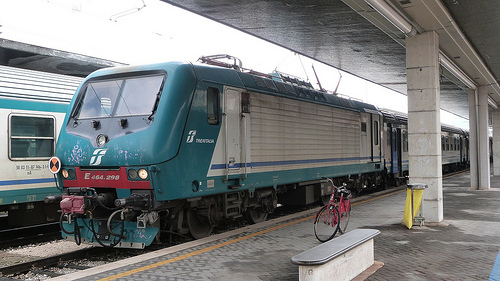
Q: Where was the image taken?
A: It was taken at the train station.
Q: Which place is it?
A: It is a train station.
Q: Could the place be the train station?
A: Yes, it is the train station.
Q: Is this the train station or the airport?
A: It is the train station.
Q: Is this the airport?
A: No, it is the train station.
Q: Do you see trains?
A: Yes, there is a train.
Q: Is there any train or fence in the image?
A: Yes, there is a train.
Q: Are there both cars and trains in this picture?
A: Yes, there are both a train and a car.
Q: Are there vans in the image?
A: No, there are no vans.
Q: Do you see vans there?
A: No, there are no vans.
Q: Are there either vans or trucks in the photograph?
A: No, there are no vans or trucks.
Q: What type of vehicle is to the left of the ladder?
A: The vehicle is a train.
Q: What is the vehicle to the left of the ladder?
A: The vehicle is a train.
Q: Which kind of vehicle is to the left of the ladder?
A: The vehicle is a train.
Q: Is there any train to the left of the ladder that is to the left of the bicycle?
A: Yes, there is a train to the left of the ladder.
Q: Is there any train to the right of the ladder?
A: No, the train is to the left of the ladder.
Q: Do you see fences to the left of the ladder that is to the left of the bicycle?
A: No, there is a train to the left of the ladder.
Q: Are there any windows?
A: Yes, there is a window.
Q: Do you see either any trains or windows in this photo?
A: Yes, there is a window.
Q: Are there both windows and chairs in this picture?
A: No, there is a window but no chairs.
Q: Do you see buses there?
A: No, there are no buses.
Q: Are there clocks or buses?
A: No, there are no buses or clocks.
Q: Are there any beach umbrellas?
A: No, there are no beach umbrellas.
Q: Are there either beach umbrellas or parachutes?
A: No, there are no beach umbrellas or parachutes.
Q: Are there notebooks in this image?
A: No, there are no notebooks.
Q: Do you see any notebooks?
A: No, there are no notebooks.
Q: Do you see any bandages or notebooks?
A: No, there are no notebooks or bandages.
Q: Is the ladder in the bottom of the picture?
A: Yes, the ladder is in the bottom of the image.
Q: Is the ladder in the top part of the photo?
A: No, the ladder is in the bottom of the image.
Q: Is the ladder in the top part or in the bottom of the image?
A: The ladder is in the bottom of the image.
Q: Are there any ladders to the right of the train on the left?
A: Yes, there is a ladder to the right of the train.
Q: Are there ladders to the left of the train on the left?
A: No, the ladder is to the right of the train.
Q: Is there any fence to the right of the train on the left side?
A: No, there is a ladder to the right of the train.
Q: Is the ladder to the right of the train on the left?
A: Yes, the ladder is to the right of the train.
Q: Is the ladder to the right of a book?
A: No, the ladder is to the right of the train.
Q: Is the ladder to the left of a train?
A: No, the ladder is to the right of a train.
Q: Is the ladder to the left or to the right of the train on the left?
A: The ladder is to the right of the train.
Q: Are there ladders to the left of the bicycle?
A: Yes, there is a ladder to the left of the bicycle.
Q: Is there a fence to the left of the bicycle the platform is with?
A: No, there is a ladder to the left of the bicycle.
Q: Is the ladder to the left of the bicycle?
A: Yes, the ladder is to the left of the bicycle.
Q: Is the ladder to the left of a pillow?
A: No, the ladder is to the left of the bicycle.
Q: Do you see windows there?
A: Yes, there are windows.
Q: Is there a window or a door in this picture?
A: Yes, there are windows.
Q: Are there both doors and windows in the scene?
A: Yes, there are both windows and a door.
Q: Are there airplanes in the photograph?
A: No, there are no airplanes.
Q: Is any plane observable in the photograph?
A: No, there are no airplanes.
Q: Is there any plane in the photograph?
A: No, there are no airplanes.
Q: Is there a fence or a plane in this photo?
A: No, there are no airplanes or fences.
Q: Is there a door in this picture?
A: Yes, there is a door.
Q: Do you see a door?
A: Yes, there is a door.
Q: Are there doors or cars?
A: Yes, there is a door.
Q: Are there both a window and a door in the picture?
A: Yes, there are both a door and a window.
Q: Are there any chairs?
A: No, there are no chairs.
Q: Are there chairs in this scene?
A: No, there are no chairs.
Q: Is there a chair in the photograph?
A: No, there are no chairs.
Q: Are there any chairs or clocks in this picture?
A: No, there are no chairs or clocks.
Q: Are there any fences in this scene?
A: No, there are no fences.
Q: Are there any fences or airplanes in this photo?
A: No, there are no fences or airplanes.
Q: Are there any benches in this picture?
A: Yes, there is a bench.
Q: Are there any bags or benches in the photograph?
A: Yes, there is a bench.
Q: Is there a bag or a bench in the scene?
A: Yes, there is a bench.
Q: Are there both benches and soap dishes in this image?
A: No, there is a bench but no soap dishes.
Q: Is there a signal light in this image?
A: No, there are no traffic lights.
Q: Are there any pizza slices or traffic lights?
A: No, there are no traffic lights or pizza slices.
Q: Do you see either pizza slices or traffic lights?
A: No, there are no traffic lights or pizza slices.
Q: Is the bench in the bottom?
A: Yes, the bench is in the bottom of the image.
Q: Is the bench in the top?
A: No, the bench is in the bottom of the image.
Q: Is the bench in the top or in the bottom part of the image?
A: The bench is in the bottom of the image.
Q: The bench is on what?
A: The bench is on the platform.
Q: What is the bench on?
A: The bench is on the platform.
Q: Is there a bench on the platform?
A: Yes, there is a bench on the platform.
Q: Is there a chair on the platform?
A: No, there is a bench on the platform.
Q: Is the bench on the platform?
A: Yes, the bench is on the platform.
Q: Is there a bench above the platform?
A: Yes, there is a bench above the platform.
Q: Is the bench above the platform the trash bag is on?
A: Yes, the bench is above the platform.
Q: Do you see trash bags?
A: Yes, there is a trash bag.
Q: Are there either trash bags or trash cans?
A: Yes, there is a trash bag.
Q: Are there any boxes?
A: No, there are no boxes.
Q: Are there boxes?
A: No, there are no boxes.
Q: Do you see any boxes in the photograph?
A: No, there are no boxes.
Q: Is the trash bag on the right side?
A: Yes, the trash bag is on the right of the image.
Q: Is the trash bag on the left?
A: No, the trash bag is on the right of the image.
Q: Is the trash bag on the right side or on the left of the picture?
A: The trash bag is on the right of the image.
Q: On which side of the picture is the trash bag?
A: The trash bag is on the right of the image.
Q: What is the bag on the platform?
A: The bag is a trash bag.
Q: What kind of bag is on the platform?
A: The bag is a trash bag.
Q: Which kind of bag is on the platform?
A: The bag is a trash bag.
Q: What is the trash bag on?
A: The trash bag is on the platform.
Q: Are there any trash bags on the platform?
A: Yes, there is a trash bag on the platform.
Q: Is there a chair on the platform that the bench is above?
A: No, there is a trash bag on the platform.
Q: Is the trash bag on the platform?
A: Yes, the trash bag is on the platform.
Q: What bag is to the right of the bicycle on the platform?
A: The bag is a trash bag.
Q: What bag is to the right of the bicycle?
A: The bag is a trash bag.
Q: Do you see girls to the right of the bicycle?
A: No, there is a trash bag to the right of the bicycle.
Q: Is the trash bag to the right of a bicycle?
A: Yes, the trash bag is to the right of a bicycle.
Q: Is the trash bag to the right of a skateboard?
A: No, the trash bag is to the right of a bicycle.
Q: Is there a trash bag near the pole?
A: Yes, there is a trash bag near the pole.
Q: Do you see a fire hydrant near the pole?
A: No, there is a trash bag near the pole.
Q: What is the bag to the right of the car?
A: The bag is a trash bag.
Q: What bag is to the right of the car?
A: The bag is a trash bag.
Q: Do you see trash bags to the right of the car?
A: Yes, there is a trash bag to the right of the car.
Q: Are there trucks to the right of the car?
A: No, there is a trash bag to the right of the car.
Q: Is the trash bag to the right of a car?
A: Yes, the trash bag is to the right of a car.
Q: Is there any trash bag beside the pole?
A: Yes, there is a trash bag beside the pole.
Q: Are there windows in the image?
A: Yes, there is a window.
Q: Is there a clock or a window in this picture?
A: Yes, there is a window.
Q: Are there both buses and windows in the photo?
A: No, there is a window but no buses.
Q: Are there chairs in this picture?
A: No, there are no chairs.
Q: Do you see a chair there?
A: No, there are no chairs.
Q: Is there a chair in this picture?
A: No, there are no chairs.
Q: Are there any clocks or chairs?
A: No, there are no chairs or clocks.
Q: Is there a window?
A: Yes, there is a window.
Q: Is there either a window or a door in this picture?
A: Yes, there is a window.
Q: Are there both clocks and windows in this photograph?
A: No, there is a window but no clocks.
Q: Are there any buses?
A: No, there are no buses.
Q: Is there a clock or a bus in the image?
A: No, there are no buses or clocks.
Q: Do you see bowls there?
A: No, there are no bowls.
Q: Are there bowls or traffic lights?
A: No, there are no bowls or traffic lights.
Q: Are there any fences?
A: No, there are no fences.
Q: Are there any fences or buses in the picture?
A: No, there are no fences or buses.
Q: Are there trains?
A: Yes, there is a train.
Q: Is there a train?
A: Yes, there is a train.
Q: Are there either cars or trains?
A: Yes, there is a train.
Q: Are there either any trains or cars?
A: Yes, there is a train.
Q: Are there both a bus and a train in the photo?
A: No, there is a train but no buses.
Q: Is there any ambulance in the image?
A: No, there are no ambulances.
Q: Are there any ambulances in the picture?
A: No, there are no ambulances.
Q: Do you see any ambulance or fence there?
A: No, there are no ambulances or fences.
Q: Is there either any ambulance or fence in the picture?
A: No, there are no ambulances or fences.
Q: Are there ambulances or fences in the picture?
A: No, there are no ambulances or fences.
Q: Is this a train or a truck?
A: This is a train.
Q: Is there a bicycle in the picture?
A: Yes, there is a bicycle.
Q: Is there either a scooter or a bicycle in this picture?
A: Yes, there is a bicycle.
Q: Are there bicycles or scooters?
A: Yes, there is a bicycle.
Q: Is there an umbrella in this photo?
A: No, there are no umbrellas.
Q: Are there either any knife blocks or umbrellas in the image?
A: No, there are no umbrellas or knife blocks.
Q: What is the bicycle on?
A: The bicycle is on the platform.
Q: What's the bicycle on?
A: The bicycle is on the platform.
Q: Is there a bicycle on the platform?
A: Yes, there is a bicycle on the platform.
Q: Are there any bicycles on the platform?
A: Yes, there is a bicycle on the platform.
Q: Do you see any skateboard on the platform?
A: No, there is a bicycle on the platform.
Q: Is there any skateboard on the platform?
A: No, there is a bicycle on the platform.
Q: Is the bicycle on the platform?
A: Yes, the bicycle is on the platform.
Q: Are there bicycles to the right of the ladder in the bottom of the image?
A: Yes, there is a bicycle to the right of the ladder.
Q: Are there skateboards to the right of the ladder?
A: No, there is a bicycle to the right of the ladder.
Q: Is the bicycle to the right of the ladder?
A: Yes, the bicycle is to the right of the ladder.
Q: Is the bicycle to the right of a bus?
A: No, the bicycle is to the right of the ladder.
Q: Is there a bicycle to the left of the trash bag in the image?
A: Yes, there is a bicycle to the left of the trash bag.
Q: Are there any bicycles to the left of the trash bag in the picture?
A: Yes, there is a bicycle to the left of the trash bag.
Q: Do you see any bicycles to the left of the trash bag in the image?
A: Yes, there is a bicycle to the left of the trash bag.